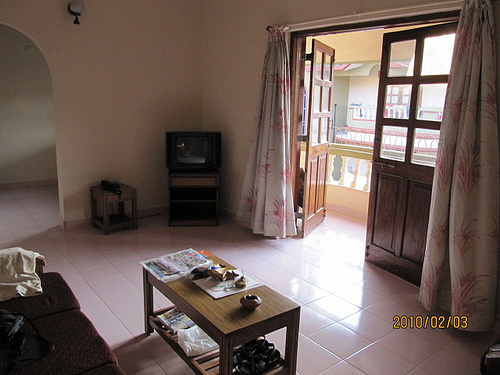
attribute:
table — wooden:
[141, 255, 302, 374]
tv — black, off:
[165, 131, 221, 173]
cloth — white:
[1, 247, 45, 302]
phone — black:
[100, 179, 121, 200]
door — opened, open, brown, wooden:
[302, 36, 336, 236]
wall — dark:
[1, 1, 213, 226]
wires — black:
[1, 308, 56, 366]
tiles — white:
[82, 241, 140, 308]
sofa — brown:
[1, 248, 124, 374]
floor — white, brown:
[1, 210, 490, 373]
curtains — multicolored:
[417, 0, 500, 332]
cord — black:
[141, 205, 166, 220]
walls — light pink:
[3, 3, 267, 235]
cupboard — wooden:
[168, 174, 218, 226]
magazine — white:
[191, 267, 268, 298]